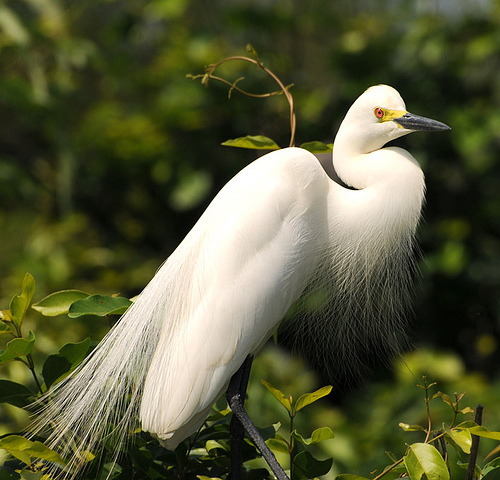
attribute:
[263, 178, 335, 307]
chest — white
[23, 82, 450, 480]
bird — green, white, resting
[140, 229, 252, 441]
wing — white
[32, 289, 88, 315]
leaf — green, small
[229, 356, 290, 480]
legs — black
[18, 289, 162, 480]
tail — white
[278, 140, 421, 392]
neck — white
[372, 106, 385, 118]
eye — red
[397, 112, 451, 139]
beak — black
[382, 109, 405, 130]
face — yellow